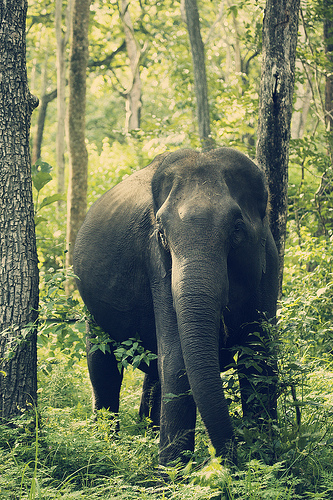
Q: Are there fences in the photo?
A: No, there are no fences.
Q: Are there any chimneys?
A: No, there are no chimneys.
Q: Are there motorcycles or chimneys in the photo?
A: No, there are no chimneys or motorcycles.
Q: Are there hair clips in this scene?
A: No, there are no hair clips.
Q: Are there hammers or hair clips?
A: No, there are no hair clips or hammers.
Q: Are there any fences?
A: No, there are no fences.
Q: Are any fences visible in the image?
A: No, there are no fences.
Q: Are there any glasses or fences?
A: No, there are no fences or glasses.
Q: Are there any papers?
A: No, there are no papers.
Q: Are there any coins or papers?
A: No, there are no papers or coins.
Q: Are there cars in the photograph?
A: No, there are no cars.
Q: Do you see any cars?
A: No, there are no cars.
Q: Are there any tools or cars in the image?
A: No, there are no cars or tools.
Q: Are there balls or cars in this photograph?
A: No, there are no cars or balls.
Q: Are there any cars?
A: No, there are no cars.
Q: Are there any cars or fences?
A: No, there are no cars or fences.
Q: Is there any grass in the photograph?
A: Yes, there is grass.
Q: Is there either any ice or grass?
A: Yes, there is grass.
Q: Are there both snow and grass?
A: No, there is grass but no snow.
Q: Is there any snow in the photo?
A: No, there is no snow.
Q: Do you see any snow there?
A: No, there is no snow.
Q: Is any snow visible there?
A: No, there is no snow.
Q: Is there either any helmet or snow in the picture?
A: No, there are no snow or helmets.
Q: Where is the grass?
A: The grass is on the ground.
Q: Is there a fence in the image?
A: No, there are no fences.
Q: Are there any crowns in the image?
A: No, there are no crowns.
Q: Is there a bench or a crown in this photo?
A: No, there are no crowns or benches.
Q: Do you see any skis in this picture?
A: No, there are no skis.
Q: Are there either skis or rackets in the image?
A: No, there are no skis or rackets.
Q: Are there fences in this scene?
A: No, there are no fences.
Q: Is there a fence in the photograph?
A: No, there are no fences.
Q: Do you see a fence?
A: No, there are no fences.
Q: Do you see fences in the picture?
A: No, there are no fences.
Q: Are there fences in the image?
A: No, there are no fences.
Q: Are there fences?
A: No, there are no fences.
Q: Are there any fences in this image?
A: No, there are no fences.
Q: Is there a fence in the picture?
A: No, there are no fences.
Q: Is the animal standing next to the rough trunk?
A: Yes, the animal is standing next to the trunk.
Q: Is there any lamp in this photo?
A: No, there are no lamps.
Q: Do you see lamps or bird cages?
A: No, there are no lamps or bird cages.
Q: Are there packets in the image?
A: No, there are no packets.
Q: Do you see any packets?
A: No, there are no packets.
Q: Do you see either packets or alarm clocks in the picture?
A: No, there are no packets or alarm clocks.